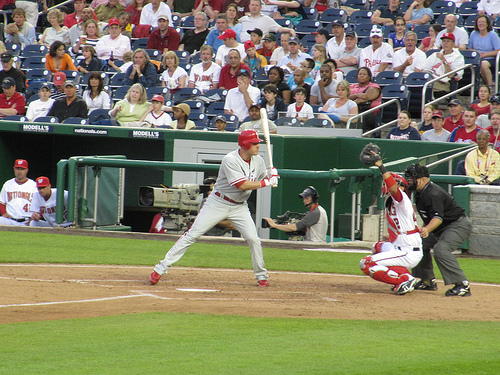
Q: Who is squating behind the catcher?
A: Umpire.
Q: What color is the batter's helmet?
A: Red.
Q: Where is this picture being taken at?
A: Baseball field.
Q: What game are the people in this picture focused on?
A: Baseball.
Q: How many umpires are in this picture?
A: 1.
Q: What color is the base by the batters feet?
A: White.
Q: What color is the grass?
A: Green.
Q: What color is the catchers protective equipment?
A: Red.